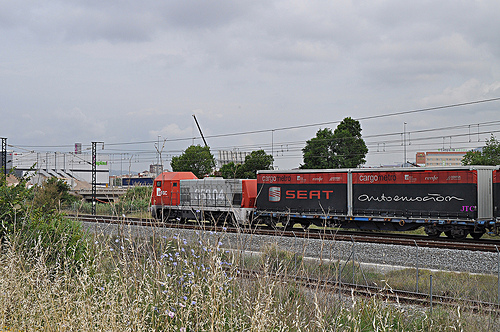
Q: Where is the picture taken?
A: Railway.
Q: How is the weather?
A: Overcast.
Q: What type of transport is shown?
A: Train.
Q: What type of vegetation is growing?
A: Grass and trees.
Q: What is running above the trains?
A: Electrical wires.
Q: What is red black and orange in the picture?
A: A train.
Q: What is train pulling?
A: Carts.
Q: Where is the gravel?
A: Around track.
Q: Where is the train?
A: On tracks.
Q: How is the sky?
A: Overcast.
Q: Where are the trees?
A: Behind train.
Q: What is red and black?
A: Box car.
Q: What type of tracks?
A: Train.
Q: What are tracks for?
A: Train.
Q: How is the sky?
A: Cloudy.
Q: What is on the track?
A: A long train.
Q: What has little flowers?
A: Weeds.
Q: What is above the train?
A: The power lines.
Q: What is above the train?
A: The cloudy sky.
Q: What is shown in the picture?
A: The track for the train.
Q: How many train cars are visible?
A: Three.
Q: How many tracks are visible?
A: Two.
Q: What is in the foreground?
A: Grass.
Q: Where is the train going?
A: To the left.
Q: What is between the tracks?
A: Gravel.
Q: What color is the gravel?
A: Gray.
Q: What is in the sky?
A: Clouds.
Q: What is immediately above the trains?
A: Power lines.